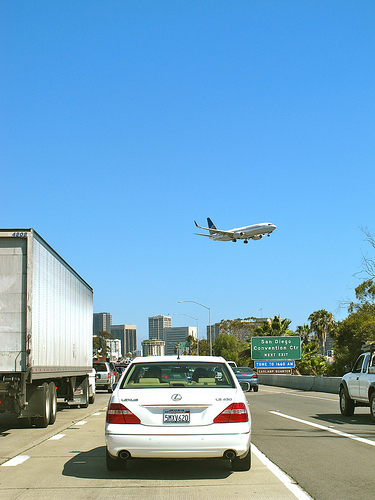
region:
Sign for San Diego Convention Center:
[239, 321, 308, 358]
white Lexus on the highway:
[99, 348, 269, 477]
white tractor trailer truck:
[0, 225, 103, 436]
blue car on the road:
[217, 358, 267, 391]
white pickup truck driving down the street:
[330, 338, 373, 434]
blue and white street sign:
[245, 354, 301, 371]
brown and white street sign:
[252, 366, 298, 377]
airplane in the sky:
[175, 199, 307, 269]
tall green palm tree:
[304, 300, 334, 366]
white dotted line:
[0, 400, 114, 485]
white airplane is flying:
[190, 218, 268, 264]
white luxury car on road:
[102, 347, 286, 497]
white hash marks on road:
[10, 398, 99, 472]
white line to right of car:
[198, 380, 319, 494]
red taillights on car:
[97, 383, 265, 441]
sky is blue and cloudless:
[112, 26, 227, 181]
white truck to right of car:
[326, 344, 373, 415]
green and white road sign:
[250, 329, 304, 363]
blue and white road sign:
[234, 360, 293, 369]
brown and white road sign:
[254, 357, 290, 391]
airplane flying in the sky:
[192, 210, 281, 251]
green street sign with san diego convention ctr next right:
[248, 335, 301, 363]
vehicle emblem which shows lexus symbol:
[169, 392, 186, 401]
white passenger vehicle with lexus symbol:
[104, 351, 256, 473]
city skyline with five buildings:
[90, 308, 227, 354]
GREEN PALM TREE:
[307, 306, 338, 359]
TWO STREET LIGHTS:
[163, 296, 217, 359]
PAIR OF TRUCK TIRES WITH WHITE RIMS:
[23, 379, 59, 432]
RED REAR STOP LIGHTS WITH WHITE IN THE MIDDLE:
[210, 396, 249, 428]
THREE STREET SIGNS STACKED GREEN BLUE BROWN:
[248, 330, 303, 382]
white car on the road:
[103, 343, 251, 477]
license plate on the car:
[157, 403, 198, 428]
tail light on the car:
[210, 397, 253, 437]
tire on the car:
[101, 439, 133, 473]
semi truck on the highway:
[4, 281, 102, 392]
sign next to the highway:
[247, 332, 307, 380]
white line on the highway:
[1, 440, 28, 483]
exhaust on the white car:
[220, 443, 248, 471]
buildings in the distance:
[140, 309, 202, 355]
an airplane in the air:
[187, 174, 294, 272]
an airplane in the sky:
[171, 174, 332, 305]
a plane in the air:
[160, 187, 282, 281]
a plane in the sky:
[169, 196, 335, 286]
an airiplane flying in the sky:
[183, 178, 323, 302]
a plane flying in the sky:
[168, 201, 324, 281]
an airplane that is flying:
[191, 189, 309, 266]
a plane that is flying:
[172, 176, 295, 284]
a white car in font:
[91, 287, 287, 494]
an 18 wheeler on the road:
[3, 207, 163, 424]